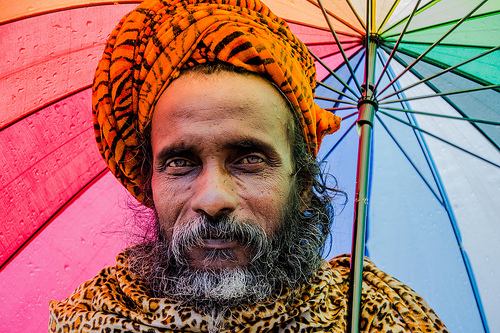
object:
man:
[43, 0, 450, 333]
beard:
[137, 215, 327, 316]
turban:
[90, 1, 343, 206]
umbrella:
[0, 0, 499, 333]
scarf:
[307, 287, 339, 325]